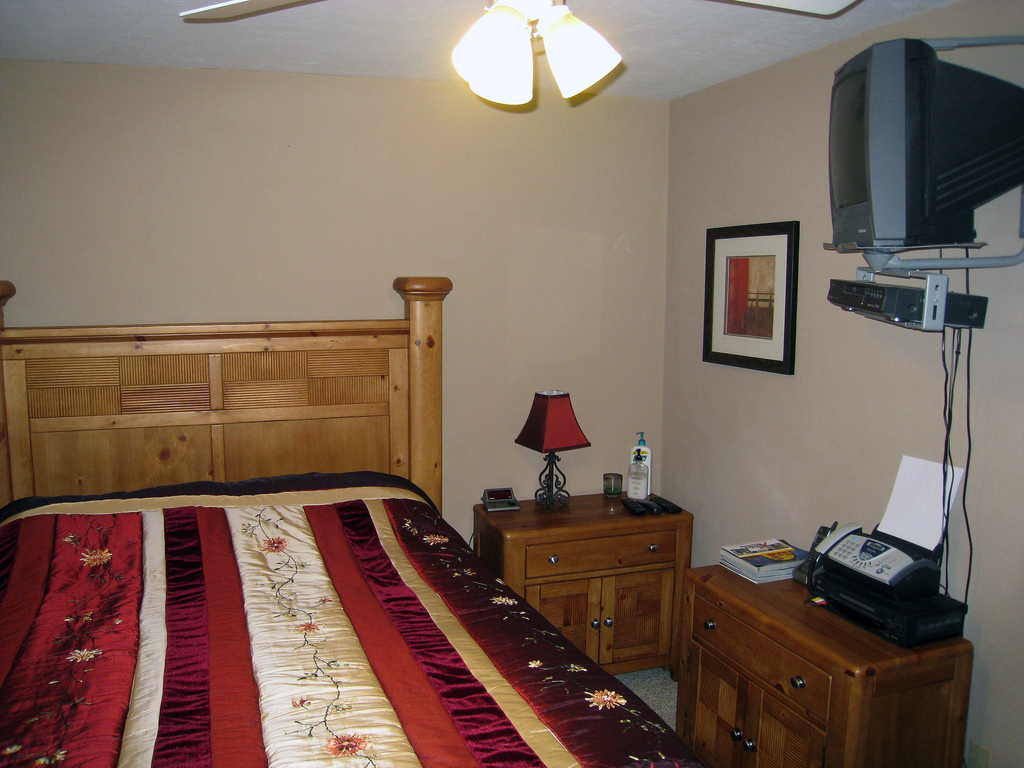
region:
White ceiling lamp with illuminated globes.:
[174, 2, 855, 108]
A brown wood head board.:
[1, 274, 457, 519]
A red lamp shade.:
[515, 389, 592, 451]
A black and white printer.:
[817, 525, 941, 605]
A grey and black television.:
[820, 37, 1021, 254]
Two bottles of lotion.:
[621, 427, 653, 501]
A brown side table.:
[469, 495, 692, 680]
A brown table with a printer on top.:
[680, 554, 972, 766]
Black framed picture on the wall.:
[699, 216, 802, 376]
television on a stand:
[756, 40, 1012, 262]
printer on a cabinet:
[782, 447, 945, 640]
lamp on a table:
[513, 389, 605, 511]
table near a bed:
[512, 520, 662, 593]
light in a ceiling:
[405, 21, 617, 124]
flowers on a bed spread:
[512, 630, 646, 744]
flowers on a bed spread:
[411, 518, 507, 635]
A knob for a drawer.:
[795, 677, 808, 691]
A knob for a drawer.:
[702, 618, 715, 628]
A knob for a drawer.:
[651, 541, 667, 557]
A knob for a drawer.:
[546, 557, 570, 573]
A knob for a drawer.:
[606, 615, 613, 629]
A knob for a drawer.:
[730, 734, 743, 744]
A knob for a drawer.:
[740, 741, 764, 755]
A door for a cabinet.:
[609, 561, 685, 661]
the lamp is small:
[501, 364, 656, 526]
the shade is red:
[499, 356, 592, 475]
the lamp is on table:
[479, 379, 701, 667]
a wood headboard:
[22, 231, 474, 590]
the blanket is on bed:
[54, 449, 563, 756]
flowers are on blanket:
[253, 503, 318, 732]